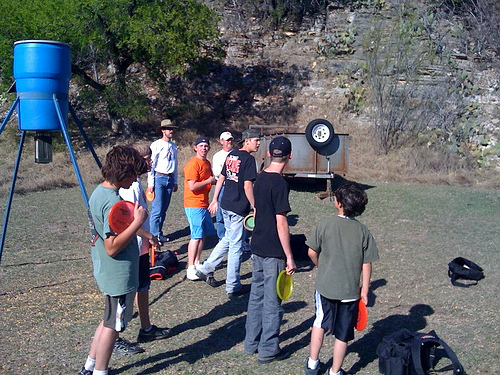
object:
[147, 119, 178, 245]
man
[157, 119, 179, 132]
hat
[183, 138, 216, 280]
man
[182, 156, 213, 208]
shirt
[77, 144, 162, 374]
person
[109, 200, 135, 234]
frisbee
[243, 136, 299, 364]
guy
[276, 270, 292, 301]
frisbee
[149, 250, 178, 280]
bag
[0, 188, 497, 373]
ground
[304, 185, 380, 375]
boy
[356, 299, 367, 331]
frisbee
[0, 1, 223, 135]
tree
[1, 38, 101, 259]
object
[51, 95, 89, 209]
leg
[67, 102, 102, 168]
leg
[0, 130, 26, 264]
leg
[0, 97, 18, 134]
leg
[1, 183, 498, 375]
grass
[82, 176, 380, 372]
group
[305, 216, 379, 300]
tee shirt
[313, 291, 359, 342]
shorts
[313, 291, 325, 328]
stripe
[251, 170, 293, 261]
tee shirt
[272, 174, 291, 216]
sleeve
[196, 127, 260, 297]
boy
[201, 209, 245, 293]
jeans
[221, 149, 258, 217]
tee shirt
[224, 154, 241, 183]
graphics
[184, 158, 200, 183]
sleeve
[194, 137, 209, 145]
cap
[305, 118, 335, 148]
tire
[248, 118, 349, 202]
trailer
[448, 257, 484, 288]
bag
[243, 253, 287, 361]
pants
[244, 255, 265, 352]
leg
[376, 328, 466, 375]
bag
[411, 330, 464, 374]
handle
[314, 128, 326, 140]
wheel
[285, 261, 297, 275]
hand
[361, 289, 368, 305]
hand